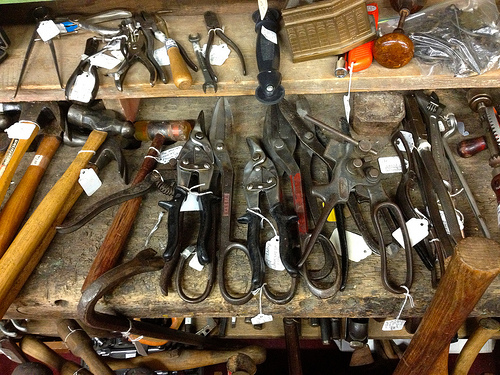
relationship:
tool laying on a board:
[163, 107, 218, 264] [0, 89, 497, 317]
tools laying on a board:
[1, 101, 134, 309] [0, 89, 497, 317]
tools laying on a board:
[78, 115, 192, 300] [0, 89, 497, 317]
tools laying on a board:
[444, 317, 497, 375] [0, 89, 497, 317]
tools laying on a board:
[278, 97, 348, 255] [0, 89, 497, 317]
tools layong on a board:
[444, 317, 497, 375] [0, 89, 497, 317]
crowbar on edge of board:
[73, 245, 239, 351] [0, 89, 497, 317]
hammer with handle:
[0, 105, 135, 304] [8, 143, 97, 286]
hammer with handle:
[6, 106, 80, 251] [8, 132, 64, 237]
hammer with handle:
[2, 103, 76, 213] [1, 128, 39, 206]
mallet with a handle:
[79, 120, 185, 290] [0, 130, 111, 299]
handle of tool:
[157, 190, 184, 260] [163, 107, 218, 264]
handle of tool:
[196, 192, 222, 264] [240, 134, 304, 287]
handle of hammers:
[0, 130, 111, 299] [0, 96, 64, 203]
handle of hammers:
[0, 130, 111, 299] [1, 108, 86, 255]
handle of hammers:
[0, 130, 111, 299] [1, 102, 134, 302]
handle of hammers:
[1, 123, 38, 202] [1, 120, 135, 316]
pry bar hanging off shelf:
[78, 246, 233, 373] [2, 278, 499, 330]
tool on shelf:
[163, 107, 218, 264] [0, 8, 499, 107]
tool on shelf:
[186, 31, 217, 92] [0, 8, 499, 107]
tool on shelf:
[63, 31, 99, 105] [0, 8, 499, 107]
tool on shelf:
[240, 134, 304, 287] [0, 8, 499, 107]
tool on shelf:
[11, 6, 65, 97] [0, 8, 499, 107]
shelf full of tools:
[49, 31, 497, 108] [40, 139, 477, 250]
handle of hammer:
[406, 238, 498, 373] [109, 114, 190, 302]